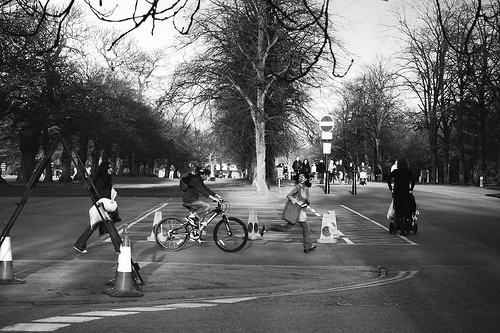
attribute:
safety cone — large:
[0, 232, 30, 282]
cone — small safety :
[105, 220, 149, 293]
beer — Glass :
[432, 294, 458, 313]